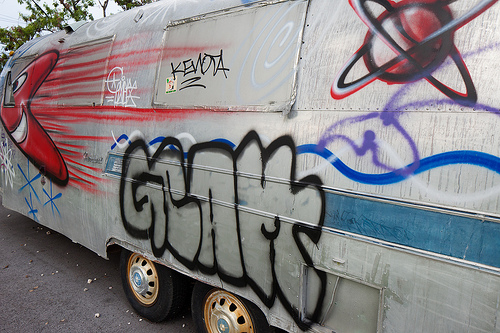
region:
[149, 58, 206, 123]
a sticker stuck on a van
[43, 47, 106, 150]
red painted sprayed on a van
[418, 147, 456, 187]
blue paint sprayed on a van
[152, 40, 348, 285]
graffiti painted on van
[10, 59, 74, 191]
a red design painted on a van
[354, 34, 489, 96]
picture of a neutron painted on a van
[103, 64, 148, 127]
white letters painted on a van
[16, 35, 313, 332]
a painted van parked in a parking lot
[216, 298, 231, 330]
There is a hubcap visible here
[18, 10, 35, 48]
There is a green tree in the distance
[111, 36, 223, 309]
This photo has a great deal of detail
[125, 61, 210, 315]
This photo has a remarkable variety to it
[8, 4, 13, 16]
There is a light blue sky here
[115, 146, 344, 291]
black graffiti on bus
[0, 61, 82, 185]
red and white graffiti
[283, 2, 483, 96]
black and red graffiti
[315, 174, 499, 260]
blue stripe on bus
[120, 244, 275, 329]
black tires on bus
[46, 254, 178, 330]
grey rocks on road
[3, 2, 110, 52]
green trees behind bus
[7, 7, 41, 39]
grey and white sky behind trees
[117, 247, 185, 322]
black wheel on tire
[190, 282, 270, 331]
black wheel on tire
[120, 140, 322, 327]
black graffiti on bus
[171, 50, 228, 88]
black graffiti on bus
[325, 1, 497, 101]
graffiti on the bus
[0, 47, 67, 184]
red face graffiti on bus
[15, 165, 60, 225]
blue star graffit on bus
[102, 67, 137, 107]
white handwriting on bus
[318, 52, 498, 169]
purple writing on bus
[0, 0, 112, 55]
green tree above bus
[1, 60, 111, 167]
graffiti on the vehicle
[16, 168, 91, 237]
graffiti on the vehicle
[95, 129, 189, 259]
graffiti on the vehicle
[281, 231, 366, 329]
graffiti on the vehicle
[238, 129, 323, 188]
graffiti on the vehicle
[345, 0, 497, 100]
graffiti on the vehicle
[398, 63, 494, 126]
graffiti on the vehicle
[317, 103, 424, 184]
graffiti on the vehicle